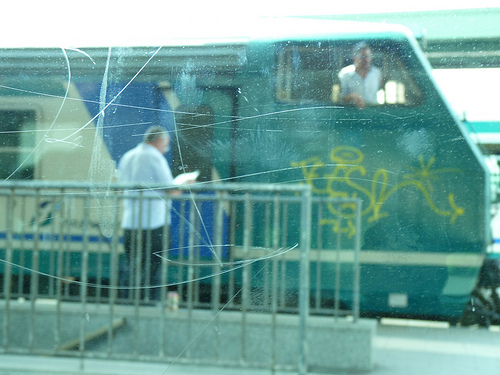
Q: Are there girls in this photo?
A: No, there are no girls.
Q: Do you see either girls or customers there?
A: No, there are no girls or customers.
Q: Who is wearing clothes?
A: The man is wearing clothes.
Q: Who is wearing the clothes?
A: The man is wearing clothes.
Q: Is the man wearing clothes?
A: Yes, the man is wearing clothes.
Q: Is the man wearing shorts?
A: No, the man is wearing clothes.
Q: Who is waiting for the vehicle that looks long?
A: The man is waiting for the train.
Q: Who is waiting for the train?
A: The man is waiting for the train.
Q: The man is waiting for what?
A: The man is waiting for the train.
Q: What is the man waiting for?
A: The man is waiting for the train.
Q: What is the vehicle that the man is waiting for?
A: The vehicle is a train.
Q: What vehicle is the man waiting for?
A: The man is waiting for the train.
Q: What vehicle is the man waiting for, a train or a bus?
A: The man is waiting for a train.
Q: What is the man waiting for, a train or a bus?
A: The man is waiting for a train.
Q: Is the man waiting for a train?
A: Yes, the man is waiting for a train.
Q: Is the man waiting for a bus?
A: No, the man is waiting for a train.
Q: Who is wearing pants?
A: The man is wearing pants.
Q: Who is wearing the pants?
A: The man is wearing pants.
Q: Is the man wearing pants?
A: Yes, the man is wearing pants.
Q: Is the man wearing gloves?
A: No, the man is wearing pants.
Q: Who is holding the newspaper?
A: The man is holding the newspaper.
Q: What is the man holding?
A: The man is holding the newspaper.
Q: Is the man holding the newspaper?
A: Yes, the man is holding the newspaper.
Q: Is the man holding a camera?
A: No, the man is holding the newspaper.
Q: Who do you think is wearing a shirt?
A: The man is wearing a shirt.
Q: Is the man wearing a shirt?
A: Yes, the man is wearing a shirt.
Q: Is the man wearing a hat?
A: No, the man is wearing a shirt.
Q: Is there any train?
A: Yes, there is a train.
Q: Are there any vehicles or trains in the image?
A: Yes, there is a train.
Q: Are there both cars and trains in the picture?
A: No, there is a train but no cars.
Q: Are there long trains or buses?
A: Yes, there is a long train.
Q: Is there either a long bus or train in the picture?
A: Yes, there is a long train.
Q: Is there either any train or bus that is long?
A: Yes, the train is long.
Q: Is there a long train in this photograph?
A: Yes, there is a long train.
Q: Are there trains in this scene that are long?
A: Yes, there is a train that is long.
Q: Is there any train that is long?
A: Yes, there is a train that is long.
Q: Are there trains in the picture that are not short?
A: Yes, there is a long train.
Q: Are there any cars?
A: No, there are no cars.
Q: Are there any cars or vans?
A: No, there are no cars or vans.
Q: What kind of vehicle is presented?
A: The vehicle is a train.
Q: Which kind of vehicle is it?
A: The vehicle is a train.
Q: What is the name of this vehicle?
A: This is a train.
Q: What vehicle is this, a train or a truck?
A: This is a train.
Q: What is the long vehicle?
A: The vehicle is a train.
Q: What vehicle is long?
A: The vehicle is a train.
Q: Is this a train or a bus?
A: This is a train.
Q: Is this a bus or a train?
A: This is a train.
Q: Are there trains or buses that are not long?
A: No, there is a train but it is long.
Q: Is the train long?
A: Yes, the train is long.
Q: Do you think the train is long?
A: Yes, the train is long.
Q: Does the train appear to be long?
A: Yes, the train is long.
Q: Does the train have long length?
A: Yes, the train is long.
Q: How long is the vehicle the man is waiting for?
A: The train is long.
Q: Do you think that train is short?
A: No, the train is long.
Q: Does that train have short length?
A: No, the train is long.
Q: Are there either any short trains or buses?
A: No, there is a train but it is long.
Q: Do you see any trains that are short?
A: No, there is a train but it is long.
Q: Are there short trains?
A: No, there is a train but it is long.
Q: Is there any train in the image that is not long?
A: No, there is a train but it is long.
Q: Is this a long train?
A: Yes, this is a long train.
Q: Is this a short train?
A: No, this is a long train.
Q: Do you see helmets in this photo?
A: No, there are no helmets.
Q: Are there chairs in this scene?
A: No, there are no chairs.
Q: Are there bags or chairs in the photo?
A: No, there are no chairs or bags.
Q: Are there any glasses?
A: No, there are no glasses.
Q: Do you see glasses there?
A: No, there are no glasses.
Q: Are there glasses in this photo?
A: No, there are no glasses.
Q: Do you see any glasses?
A: No, there are no glasses.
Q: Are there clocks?
A: No, there are no clocks.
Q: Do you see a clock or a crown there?
A: No, there are no clocks or crowns.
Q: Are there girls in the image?
A: No, there are no girls.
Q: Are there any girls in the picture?
A: No, there are no girls.